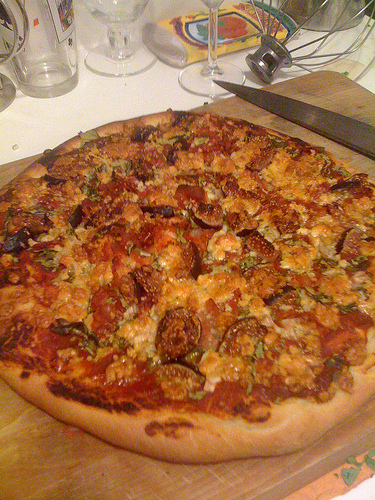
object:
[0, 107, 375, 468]
pizza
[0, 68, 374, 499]
board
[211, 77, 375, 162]
knife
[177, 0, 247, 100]
glass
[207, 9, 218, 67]
stem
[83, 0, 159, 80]
glass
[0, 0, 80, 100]
glass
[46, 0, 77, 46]
jack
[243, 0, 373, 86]
whisk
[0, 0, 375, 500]
counter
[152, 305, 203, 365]
topping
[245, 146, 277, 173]
topping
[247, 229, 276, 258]
topping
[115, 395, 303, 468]
crust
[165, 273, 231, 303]
cheese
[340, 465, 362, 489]
leaf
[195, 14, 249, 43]
picture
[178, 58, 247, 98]
bottom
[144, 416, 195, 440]
spot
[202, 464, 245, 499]
cuts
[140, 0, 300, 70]
package